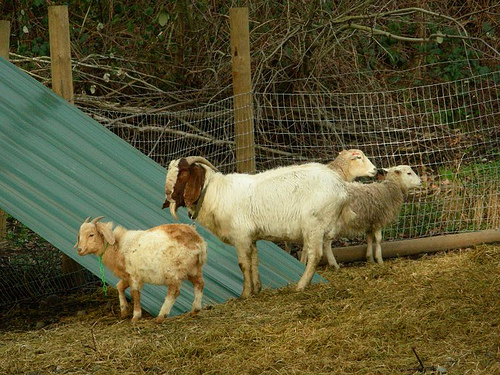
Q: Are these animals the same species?
A: No, they are sheep and goats.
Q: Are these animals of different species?
A: Yes, they are sheep and goats.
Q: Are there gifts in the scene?
A: No, there are no gifts.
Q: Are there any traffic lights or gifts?
A: No, there are no gifts or traffic lights.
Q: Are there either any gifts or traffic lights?
A: No, there are no gifts or traffic lights.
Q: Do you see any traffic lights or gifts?
A: No, there are no gifts or traffic lights.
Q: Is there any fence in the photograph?
A: Yes, there is a fence.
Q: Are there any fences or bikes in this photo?
A: Yes, there is a fence.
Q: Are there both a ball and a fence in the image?
A: No, there is a fence but no balls.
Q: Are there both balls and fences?
A: No, there is a fence but no balls.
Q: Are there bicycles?
A: No, there are no bicycles.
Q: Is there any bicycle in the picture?
A: No, there are no bicycles.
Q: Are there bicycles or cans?
A: No, there are no bicycles or cans.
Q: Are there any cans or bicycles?
A: No, there are no bicycles or cans.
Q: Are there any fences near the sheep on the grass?
A: Yes, there is a fence near the sheep.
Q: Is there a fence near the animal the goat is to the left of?
A: Yes, there is a fence near the sheep.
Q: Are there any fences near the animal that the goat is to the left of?
A: Yes, there is a fence near the sheep.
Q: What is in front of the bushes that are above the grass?
A: The fence is in front of the bushes.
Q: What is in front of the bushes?
A: The fence is in front of the bushes.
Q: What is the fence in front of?
A: The fence is in front of the shrubs.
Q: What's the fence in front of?
A: The fence is in front of the shrubs.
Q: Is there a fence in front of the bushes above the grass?
A: Yes, there is a fence in front of the bushes.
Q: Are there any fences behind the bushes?
A: No, the fence is in front of the bushes.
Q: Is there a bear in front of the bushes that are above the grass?
A: No, there is a fence in front of the shrubs.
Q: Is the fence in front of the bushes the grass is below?
A: Yes, the fence is in front of the bushes.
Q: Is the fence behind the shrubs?
A: No, the fence is in front of the shrubs.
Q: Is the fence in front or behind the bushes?
A: The fence is in front of the bushes.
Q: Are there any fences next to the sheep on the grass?
A: Yes, there is a fence next to the sheep.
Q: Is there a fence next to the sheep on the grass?
A: Yes, there is a fence next to the sheep.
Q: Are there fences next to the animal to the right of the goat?
A: Yes, there is a fence next to the sheep.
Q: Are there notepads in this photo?
A: No, there are no notepads.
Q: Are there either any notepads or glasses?
A: No, there are no notepads or glasses.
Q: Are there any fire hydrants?
A: No, there are no fire hydrants.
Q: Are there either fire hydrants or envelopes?
A: No, there are no fire hydrants or envelopes.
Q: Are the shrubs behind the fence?
A: Yes, the shrubs are behind the fence.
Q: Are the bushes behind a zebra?
A: No, the bushes are behind the fence.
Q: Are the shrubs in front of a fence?
A: No, the shrubs are behind a fence.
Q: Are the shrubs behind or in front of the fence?
A: The shrubs are behind the fence.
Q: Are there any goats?
A: Yes, there is a goat.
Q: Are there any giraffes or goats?
A: Yes, there is a goat.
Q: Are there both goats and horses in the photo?
A: No, there is a goat but no horses.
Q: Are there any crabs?
A: No, there are no crabs.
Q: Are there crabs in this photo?
A: No, there are no crabs.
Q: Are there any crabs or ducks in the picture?
A: No, there are no crabs or ducks.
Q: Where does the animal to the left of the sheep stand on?
A: The goat stands on the grass.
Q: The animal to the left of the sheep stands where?
A: The goat stands on the grass.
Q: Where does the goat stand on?
A: The goat stands on the grass.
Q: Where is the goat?
A: The goat is on the grass.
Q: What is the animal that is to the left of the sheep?
A: The animal is a goat.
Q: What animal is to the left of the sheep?
A: The animal is a goat.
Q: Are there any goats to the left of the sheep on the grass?
A: Yes, there is a goat to the left of the sheep.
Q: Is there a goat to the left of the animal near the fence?
A: Yes, there is a goat to the left of the sheep.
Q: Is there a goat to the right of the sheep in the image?
A: No, the goat is to the left of the sheep.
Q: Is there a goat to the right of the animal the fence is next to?
A: No, the goat is to the left of the sheep.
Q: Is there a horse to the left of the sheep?
A: No, there is a goat to the left of the sheep.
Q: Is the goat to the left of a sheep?
A: Yes, the goat is to the left of a sheep.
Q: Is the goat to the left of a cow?
A: No, the goat is to the left of a sheep.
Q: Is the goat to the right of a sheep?
A: No, the goat is to the left of a sheep.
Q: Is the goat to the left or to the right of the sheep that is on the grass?
A: The goat is to the left of the sheep.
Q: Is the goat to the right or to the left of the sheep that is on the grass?
A: The goat is to the left of the sheep.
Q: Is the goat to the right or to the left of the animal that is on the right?
A: The goat is to the left of the sheep.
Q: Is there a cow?
A: No, there are no cows.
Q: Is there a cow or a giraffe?
A: No, there are no cows or giraffes.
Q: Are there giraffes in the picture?
A: No, there are no giraffes.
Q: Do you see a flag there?
A: No, there are no flags.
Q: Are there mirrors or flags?
A: No, there are no flags or mirrors.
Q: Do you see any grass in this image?
A: Yes, there is grass.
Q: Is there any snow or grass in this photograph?
A: Yes, there is grass.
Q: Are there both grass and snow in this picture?
A: No, there is grass but no snow.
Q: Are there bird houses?
A: No, there are no bird houses.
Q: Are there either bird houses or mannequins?
A: No, there are no bird houses or mannequins.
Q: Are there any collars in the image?
A: Yes, there is a collar.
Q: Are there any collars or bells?
A: Yes, there is a collar.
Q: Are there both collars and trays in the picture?
A: No, there is a collar but no trays.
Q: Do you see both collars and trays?
A: No, there is a collar but no trays.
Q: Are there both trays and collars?
A: No, there is a collar but no trays.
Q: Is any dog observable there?
A: No, there are no dogs.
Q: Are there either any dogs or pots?
A: No, there are no dogs or pots.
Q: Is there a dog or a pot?
A: No, there are no dogs or pots.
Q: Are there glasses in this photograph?
A: No, there are no glasses.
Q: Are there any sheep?
A: Yes, there is a sheep.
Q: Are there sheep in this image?
A: Yes, there is a sheep.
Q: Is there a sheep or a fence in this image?
A: Yes, there is a sheep.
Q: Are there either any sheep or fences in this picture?
A: Yes, there is a sheep.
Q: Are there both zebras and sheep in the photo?
A: No, there is a sheep but no zebras.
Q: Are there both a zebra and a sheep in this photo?
A: No, there is a sheep but no zebras.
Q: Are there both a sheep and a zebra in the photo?
A: No, there is a sheep but no zebras.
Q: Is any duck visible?
A: No, there are no ducks.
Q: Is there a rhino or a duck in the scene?
A: No, there are no ducks or rhinos.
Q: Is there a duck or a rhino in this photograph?
A: No, there are no ducks or rhinos.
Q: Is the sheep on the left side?
A: No, the sheep is on the right of the image.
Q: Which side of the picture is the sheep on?
A: The sheep is on the right of the image.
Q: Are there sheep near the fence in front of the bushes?
A: Yes, there is a sheep near the fence.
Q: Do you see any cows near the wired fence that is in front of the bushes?
A: No, there is a sheep near the fence.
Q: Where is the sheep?
A: The sheep is on the grass.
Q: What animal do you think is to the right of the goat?
A: The animal is a sheep.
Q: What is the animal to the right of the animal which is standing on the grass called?
A: The animal is a sheep.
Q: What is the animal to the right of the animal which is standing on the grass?
A: The animal is a sheep.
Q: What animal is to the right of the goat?
A: The animal is a sheep.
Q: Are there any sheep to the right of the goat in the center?
A: Yes, there is a sheep to the right of the goat.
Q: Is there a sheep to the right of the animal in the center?
A: Yes, there is a sheep to the right of the goat.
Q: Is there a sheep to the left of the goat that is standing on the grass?
A: No, the sheep is to the right of the goat.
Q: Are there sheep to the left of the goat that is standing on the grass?
A: No, the sheep is to the right of the goat.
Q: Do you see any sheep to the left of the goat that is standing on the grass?
A: No, the sheep is to the right of the goat.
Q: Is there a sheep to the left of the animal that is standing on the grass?
A: No, the sheep is to the right of the goat.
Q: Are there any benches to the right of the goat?
A: No, there is a sheep to the right of the goat.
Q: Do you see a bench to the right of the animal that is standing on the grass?
A: No, there is a sheep to the right of the goat.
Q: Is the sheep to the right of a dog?
A: No, the sheep is to the right of the goat.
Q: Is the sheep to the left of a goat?
A: No, the sheep is to the right of a goat.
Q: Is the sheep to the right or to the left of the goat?
A: The sheep is to the right of the goat.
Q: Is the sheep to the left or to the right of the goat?
A: The sheep is to the right of the goat.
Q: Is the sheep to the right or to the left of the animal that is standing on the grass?
A: The sheep is to the right of the goat.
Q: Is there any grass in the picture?
A: Yes, there is grass.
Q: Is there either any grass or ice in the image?
A: Yes, there is grass.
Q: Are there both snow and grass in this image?
A: No, there is grass but no snow.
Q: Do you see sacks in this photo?
A: No, there are no sacks.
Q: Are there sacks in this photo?
A: No, there are no sacks.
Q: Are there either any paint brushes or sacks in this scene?
A: No, there are no sacks or paint brushes.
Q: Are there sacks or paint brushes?
A: No, there are no sacks or paint brushes.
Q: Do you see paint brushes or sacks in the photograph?
A: No, there are no sacks or paint brushes.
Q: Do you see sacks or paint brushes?
A: No, there are no sacks or paint brushes.